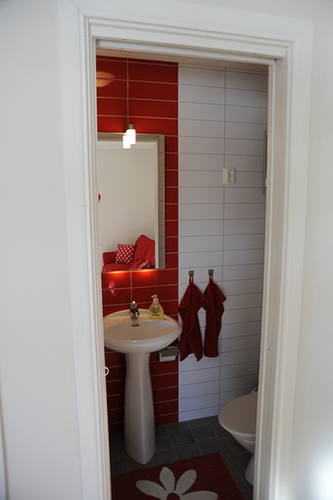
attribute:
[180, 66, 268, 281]
wall — white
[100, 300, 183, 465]
pedestal sink — white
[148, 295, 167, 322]
hand soap — yellow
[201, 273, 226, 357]
towel — red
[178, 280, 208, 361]
towel — red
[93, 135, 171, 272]
mirror — bathroom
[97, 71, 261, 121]
wall — white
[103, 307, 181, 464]
sink — toilet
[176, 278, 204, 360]
towel — red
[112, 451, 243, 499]
rug — red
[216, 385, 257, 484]
toilet — white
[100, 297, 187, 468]
sink — white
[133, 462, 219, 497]
flower — white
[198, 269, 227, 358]
towel — red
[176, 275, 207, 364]
towel — red